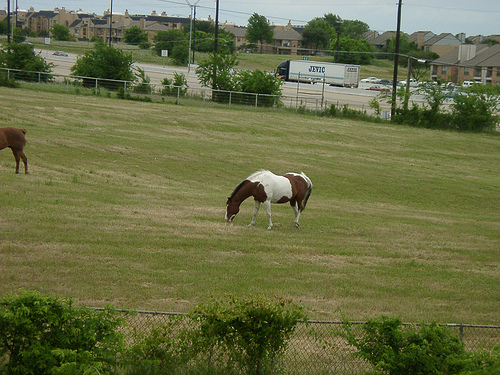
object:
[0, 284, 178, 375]
bush fence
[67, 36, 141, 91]
plants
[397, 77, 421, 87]
vehicle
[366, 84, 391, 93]
vehicle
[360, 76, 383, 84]
vehicle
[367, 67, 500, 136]
lot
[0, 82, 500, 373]
grass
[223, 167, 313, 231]
horse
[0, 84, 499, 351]
field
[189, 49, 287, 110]
plant life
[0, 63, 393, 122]
fence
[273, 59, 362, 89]
truck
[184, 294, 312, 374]
bush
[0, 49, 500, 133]
road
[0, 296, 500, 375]
fence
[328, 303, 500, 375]
bush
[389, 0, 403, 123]
pole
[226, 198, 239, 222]
face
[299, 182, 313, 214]
tail